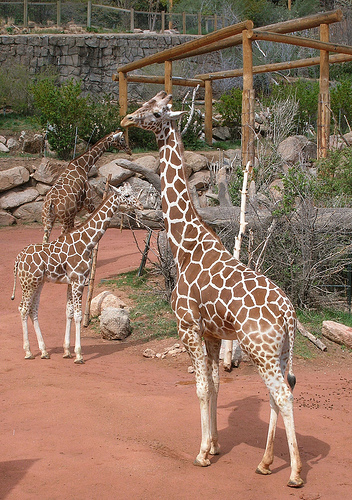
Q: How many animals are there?
A: Three.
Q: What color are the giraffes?
A: White and Brown.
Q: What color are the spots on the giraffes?
A: Brown.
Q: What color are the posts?
A: Brown.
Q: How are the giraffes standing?
A: Upright.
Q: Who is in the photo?
A: No one.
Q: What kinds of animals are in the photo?
A: Giraffes.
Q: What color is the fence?
A: Grey.